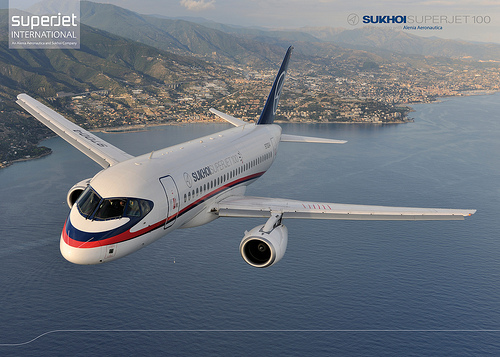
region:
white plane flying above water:
[19, 44, 479, 267]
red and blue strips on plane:
[54, 154, 275, 253]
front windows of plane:
[77, 185, 139, 222]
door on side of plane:
[160, 177, 180, 224]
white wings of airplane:
[14, 92, 476, 233]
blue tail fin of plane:
[250, 41, 290, 123]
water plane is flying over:
[25, 108, 498, 346]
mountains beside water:
[10, 12, 475, 92]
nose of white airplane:
[55, 232, 82, 269]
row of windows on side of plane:
[180, 146, 275, 209]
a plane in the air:
[16, 42, 481, 277]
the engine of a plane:
[234, 217, 290, 270]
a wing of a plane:
[223, 186, 478, 226]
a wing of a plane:
[7, 85, 132, 162]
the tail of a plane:
[259, 41, 296, 131]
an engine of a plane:
[60, 178, 90, 204]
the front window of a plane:
[73, 181, 150, 223]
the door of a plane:
[155, 170, 183, 226]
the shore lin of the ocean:
[108, 105, 199, 133]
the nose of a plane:
[53, 212, 126, 269]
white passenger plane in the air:
[11, 73, 470, 276]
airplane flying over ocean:
[20, 71, 450, 303]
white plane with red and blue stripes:
[46, 86, 350, 268]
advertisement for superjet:
[20, 6, 491, 303]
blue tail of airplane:
[257, 38, 304, 133]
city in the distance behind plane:
[115, 44, 481, 126]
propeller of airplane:
[227, 225, 297, 272]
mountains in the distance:
[10, 15, 327, 97]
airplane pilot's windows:
[60, 183, 152, 233]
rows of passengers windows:
[174, 142, 286, 206]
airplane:
[9, 64, 455, 295]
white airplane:
[15, 76, 442, 293]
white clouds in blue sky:
[88, 8, 138, 49]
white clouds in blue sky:
[160, 30, 200, 66]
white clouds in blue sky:
[220, 12, 251, 63]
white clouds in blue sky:
[252, 12, 313, 43]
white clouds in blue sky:
[315, 12, 341, 33]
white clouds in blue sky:
[333, 35, 370, 68]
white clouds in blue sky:
[385, 27, 410, 53]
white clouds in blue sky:
[457, 13, 497, 42]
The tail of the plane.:
[261, 35, 293, 125]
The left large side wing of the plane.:
[12, 89, 127, 166]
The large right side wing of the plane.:
[223, 185, 475, 229]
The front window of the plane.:
[82, 186, 144, 221]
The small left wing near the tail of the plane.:
[207, 102, 245, 129]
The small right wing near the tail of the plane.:
[282, 124, 345, 150]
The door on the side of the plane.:
[161, 167, 181, 229]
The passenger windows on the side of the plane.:
[167, 146, 281, 205]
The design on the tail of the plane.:
[276, 68, 284, 121]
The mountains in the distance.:
[7, 2, 499, 79]